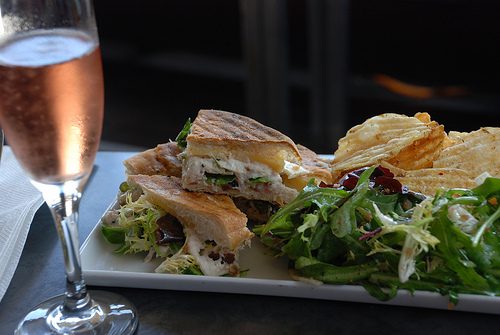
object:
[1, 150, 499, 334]
grey table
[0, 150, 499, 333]
countertop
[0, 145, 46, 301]
napkin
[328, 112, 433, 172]
chips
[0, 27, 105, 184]
wine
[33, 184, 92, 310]
stem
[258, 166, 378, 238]
lettuce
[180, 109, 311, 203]
food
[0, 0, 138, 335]
wine glass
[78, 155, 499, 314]
plate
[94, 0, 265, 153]
door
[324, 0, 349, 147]
trim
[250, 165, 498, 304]
salad